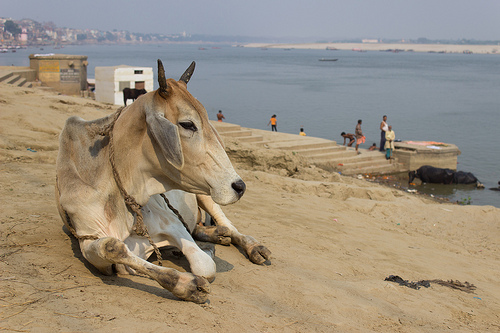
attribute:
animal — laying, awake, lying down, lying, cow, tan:
[52, 81, 279, 315]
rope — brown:
[100, 160, 198, 259]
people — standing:
[266, 88, 398, 160]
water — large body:
[299, 80, 469, 102]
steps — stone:
[306, 138, 392, 184]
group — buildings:
[31, 41, 145, 105]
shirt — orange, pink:
[270, 119, 277, 126]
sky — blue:
[267, 1, 387, 40]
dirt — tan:
[281, 204, 380, 256]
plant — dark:
[381, 274, 474, 298]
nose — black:
[224, 178, 251, 199]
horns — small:
[153, 61, 198, 95]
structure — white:
[96, 62, 151, 113]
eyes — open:
[180, 117, 196, 138]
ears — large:
[145, 53, 204, 98]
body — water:
[343, 68, 448, 114]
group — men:
[333, 109, 400, 166]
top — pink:
[268, 117, 279, 124]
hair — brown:
[377, 115, 389, 125]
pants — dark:
[269, 123, 280, 135]